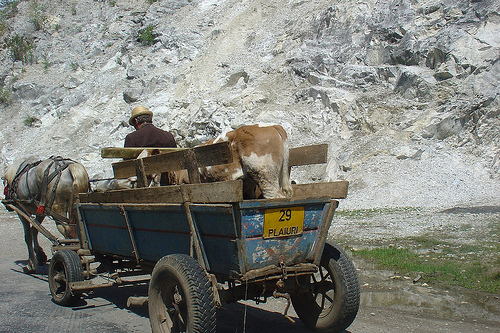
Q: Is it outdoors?
A: Yes, it is outdoors.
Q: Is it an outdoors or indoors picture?
A: It is outdoors.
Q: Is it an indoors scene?
A: No, it is outdoors.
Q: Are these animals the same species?
A: No, they are horses and cows.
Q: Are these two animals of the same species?
A: No, they are horses and cows.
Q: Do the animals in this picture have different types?
A: Yes, they are horses and cows.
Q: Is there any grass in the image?
A: Yes, there is grass.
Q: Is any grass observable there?
A: Yes, there is grass.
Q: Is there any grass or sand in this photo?
A: Yes, there is grass.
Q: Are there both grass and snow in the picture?
A: No, there is grass but no snow.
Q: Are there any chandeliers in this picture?
A: No, there are no chandeliers.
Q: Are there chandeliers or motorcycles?
A: No, there are no chandeliers or motorcycles.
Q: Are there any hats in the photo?
A: Yes, there is a hat.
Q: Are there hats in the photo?
A: Yes, there is a hat.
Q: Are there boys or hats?
A: Yes, there is a hat.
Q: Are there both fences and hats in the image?
A: Yes, there are both a hat and a fence.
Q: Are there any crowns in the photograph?
A: No, there are no crowns.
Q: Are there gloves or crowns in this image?
A: No, there are no crowns or gloves.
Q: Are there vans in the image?
A: No, there are no vans.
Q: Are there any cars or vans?
A: No, there are no vans or cars.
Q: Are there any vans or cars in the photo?
A: No, there are no vans or cars.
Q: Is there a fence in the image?
A: Yes, there is a fence.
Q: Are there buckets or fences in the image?
A: Yes, there is a fence.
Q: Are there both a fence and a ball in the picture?
A: No, there is a fence but no balls.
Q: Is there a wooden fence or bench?
A: Yes, there is a wood fence.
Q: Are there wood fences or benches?
A: Yes, there is a wood fence.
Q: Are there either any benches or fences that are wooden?
A: Yes, the fence is wooden.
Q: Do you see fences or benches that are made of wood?
A: Yes, the fence is made of wood.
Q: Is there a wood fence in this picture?
A: Yes, there is a wood fence.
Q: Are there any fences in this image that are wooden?
A: Yes, there is a fence that is wooden.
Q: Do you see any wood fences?
A: Yes, there is a fence that is made of wood.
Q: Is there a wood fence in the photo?
A: Yes, there is a fence that is made of wood.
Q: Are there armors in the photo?
A: No, there are no armors.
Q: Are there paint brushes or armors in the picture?
A: No, there are no armors or paint brushes.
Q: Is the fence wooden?
A: Yes, the fence is wooden.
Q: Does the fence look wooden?
A: Yes, the fence is wooden.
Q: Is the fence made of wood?
A: Yes, the fence is made of wood.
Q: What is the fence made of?
A: The fence is made of wood.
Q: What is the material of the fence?
A: The fence is made of wood.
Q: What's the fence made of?
A: The fence is made of wood.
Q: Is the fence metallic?
A: No, the fence is wooden.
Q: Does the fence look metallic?
A: No, the fence is wooden.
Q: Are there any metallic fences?
A: No, there is a fence but it is wooden.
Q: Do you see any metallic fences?
A: No, there is a fence but it is wooden.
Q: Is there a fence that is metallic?
A: No, there is a fence but it is wooden.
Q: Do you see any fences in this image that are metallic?
A: No, there is a fence but it is wooden.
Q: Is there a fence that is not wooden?
A: No, there is a fence but it is wooden.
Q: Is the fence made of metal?
A: No, the fence is made of wood.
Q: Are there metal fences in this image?
A: No, there is a fence but it is made of wood.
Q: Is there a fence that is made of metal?
A: No, there is a fence but it is made of wood.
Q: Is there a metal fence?
A: No, there is a fence but it is made of wood.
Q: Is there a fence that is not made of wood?
A: No, there is a fence but it is made of wood.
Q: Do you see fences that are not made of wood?
A: No, there is a fence but it is made of wood.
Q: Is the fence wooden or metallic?
A: The fence is wooden.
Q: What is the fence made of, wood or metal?
A: The fence is made of wood.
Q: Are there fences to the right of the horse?
A: Yes, there is a fence to the right of the horse.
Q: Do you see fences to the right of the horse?
A: Yes, there is a fence to the right of the horse.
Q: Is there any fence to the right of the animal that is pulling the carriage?
A: Yes, there is a fence to the right of the horse.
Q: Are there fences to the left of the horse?
A: No, the fence is to the right of the horse.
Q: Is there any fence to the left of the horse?
A: No, the fence is to the right of the horse.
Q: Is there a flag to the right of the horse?
A: No, there is a fence to the right of the horse.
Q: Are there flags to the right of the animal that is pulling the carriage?
A: No, there is a fence to the right of the horse.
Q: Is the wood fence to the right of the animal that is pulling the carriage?
A: Yes, the fence is to the right of the horse.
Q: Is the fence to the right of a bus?
A: No, the fence is to the right of the horse.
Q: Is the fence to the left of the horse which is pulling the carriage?
A: No, the fence is to the right of the horse.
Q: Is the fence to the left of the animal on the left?
A: No, the fence is to the right of the horse.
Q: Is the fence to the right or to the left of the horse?
A: The fence is to the right of the horse.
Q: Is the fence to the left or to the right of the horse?
A: The fence is to the right of the horse.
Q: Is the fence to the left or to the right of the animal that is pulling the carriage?
A: The fence is to the right of the horse.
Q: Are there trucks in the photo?
A: No, there are no trucks.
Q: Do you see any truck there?
A: No, there are no trucks.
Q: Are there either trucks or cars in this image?
A: No, there are no trucks or cars.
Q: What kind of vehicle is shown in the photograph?
A: The vehicle is a carriage.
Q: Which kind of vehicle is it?
A: The vehicle is a carriage.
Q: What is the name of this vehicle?
A: This is a carriage.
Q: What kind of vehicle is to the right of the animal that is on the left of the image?
A: The vehicle is a carriage.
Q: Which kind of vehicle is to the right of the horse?
A: The vehicle is a carriage.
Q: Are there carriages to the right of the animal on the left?
A: Yes, there is a carriage to the right of the horse.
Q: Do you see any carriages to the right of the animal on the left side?
A: Yes, there is a carriage to the right of the horse.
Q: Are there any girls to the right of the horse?
A: No, there is a carriage to the right of the horse.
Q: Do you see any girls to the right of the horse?
A: No, there is a carriage to the right of the horse.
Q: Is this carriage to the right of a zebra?
A: No, the carriage is to the right of the horse.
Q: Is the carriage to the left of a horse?
A: No, the carriage is to the right of a horse.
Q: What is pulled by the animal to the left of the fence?
A: The carriage is pulled by the horse.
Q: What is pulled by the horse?
A: The carriage is pulled by the horse.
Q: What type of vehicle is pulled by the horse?
A: The vehicle is a carriage.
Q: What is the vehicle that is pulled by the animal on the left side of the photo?
A: The vehicle is a carriage.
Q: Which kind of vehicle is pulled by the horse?
A: The vehicle is a carriage.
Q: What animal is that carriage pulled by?
A: The carriage is pulled by the horse.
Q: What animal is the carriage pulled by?
A: The carriage is pulled by the horse.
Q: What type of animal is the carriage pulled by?
A: The carriage is pulled by the horse.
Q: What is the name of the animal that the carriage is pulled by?
A: The animal is a horse.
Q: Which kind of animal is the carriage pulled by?
A: The carriage is pulled by the horse.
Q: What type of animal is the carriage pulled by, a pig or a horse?
A: The carriage is pulled by a horse.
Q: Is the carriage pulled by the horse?
A: Yes, the carriage is pulled by the horse.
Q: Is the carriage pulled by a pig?
A: No, the carriage is pulled by the horse.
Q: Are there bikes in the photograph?
A: No, there are no bikes.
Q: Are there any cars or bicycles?
A: No, there are no bicycles or cars.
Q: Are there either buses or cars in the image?
A: No, there are no buses or cars.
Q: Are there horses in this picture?
A: Yes, there is a horse.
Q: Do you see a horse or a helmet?
A: Yes, there is a horse.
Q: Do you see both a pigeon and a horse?
A: No, there is a horse but no pigeons.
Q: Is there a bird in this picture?
A: No, there are no birds.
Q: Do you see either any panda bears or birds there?
A: No, there are no birds or panda bears.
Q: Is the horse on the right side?
A: No, the horse is on the left of the image.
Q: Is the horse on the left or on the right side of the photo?
A: The horse is on the left of the image.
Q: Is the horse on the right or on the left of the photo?
A: The horse is on the left of the image.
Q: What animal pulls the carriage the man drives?
A: The horse pulls the carriage.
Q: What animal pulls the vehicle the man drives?
A: The horse pulls the carriage.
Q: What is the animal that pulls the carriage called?
A: The animal is a horse.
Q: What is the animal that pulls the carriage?
A: The animal is a horse.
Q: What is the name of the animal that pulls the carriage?
A: The animal is a horse.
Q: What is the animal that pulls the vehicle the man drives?
A: The animal is a horse.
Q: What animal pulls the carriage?
A: The animal is a horse.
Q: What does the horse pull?
A: The horse pulls the carriage.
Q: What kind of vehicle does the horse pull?
A: The horse pulls the carriage.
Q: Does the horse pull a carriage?
A: Yes, the horse pulls a carriage.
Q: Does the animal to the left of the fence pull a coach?
A: No, the horse pulls a carriage.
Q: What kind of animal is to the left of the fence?
A: The animal is a horse.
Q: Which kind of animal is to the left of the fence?
A: The animal is a horse.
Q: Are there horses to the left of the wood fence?
A: Yes, there is a horse to the left of the fence.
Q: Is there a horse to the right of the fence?
A: No, the horse is to the left of the fence.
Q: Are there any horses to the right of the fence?
A: No, the horse is to the left of the fence.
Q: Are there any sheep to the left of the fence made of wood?
A: No, there is a horse to the left of the fence.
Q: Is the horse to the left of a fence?
A: Yes, the horse is to the left of a fence.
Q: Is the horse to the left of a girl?
A: No, the horse is to the left of a fence.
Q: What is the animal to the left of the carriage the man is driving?
A: The animal is a horse.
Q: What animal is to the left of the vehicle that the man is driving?
A: The animal is a horse.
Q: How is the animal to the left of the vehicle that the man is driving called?
A: The animal is a horse.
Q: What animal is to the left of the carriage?
A: The animal is a horse.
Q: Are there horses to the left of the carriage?
A: Yes, there is a horse to the left of the carriage.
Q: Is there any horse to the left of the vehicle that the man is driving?
A: Yes, there is a horse to the left of the carriage.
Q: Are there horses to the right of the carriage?
A: No, the horse is to the left of the carriage.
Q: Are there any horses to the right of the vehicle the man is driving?
A: No, the horse is to the left of the carriage.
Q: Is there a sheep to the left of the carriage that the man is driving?
A: No, there is a horse to the left of the carriage.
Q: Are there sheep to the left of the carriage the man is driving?
A: No, there is a horse to the left of the carriage.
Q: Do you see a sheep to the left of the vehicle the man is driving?
A: No, there is a horse to the left of the carriage.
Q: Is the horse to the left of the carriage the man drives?
A: Yes, the horse is to the left of the carriage.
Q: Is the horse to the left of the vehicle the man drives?
A: Yes, the horse is to the left of the carriage.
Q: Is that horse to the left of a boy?
A: No, the horse is to the left of the carriage.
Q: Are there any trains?
A: No, there are no trains.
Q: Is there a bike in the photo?
A: No, there are no bikes.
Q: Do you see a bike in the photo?
A: No, there are no bikes.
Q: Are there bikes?
A: No, there are no bikes.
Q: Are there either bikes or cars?
A: No, there are no bikes or cars.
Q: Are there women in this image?
A: No, there are no women.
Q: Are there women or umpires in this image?
A: No, there are no women or umpires.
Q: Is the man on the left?
A: Yes, the man is on the left of the image.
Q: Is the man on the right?
A: No, the man is on the left of the image.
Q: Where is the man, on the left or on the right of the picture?
A: The man is on the left of the image.